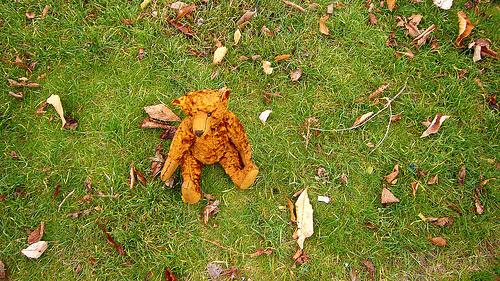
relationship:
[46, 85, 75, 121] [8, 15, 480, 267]
leaf on grass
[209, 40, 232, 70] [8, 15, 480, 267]
leaf on grass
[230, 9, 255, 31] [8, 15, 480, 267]
leaf on grass